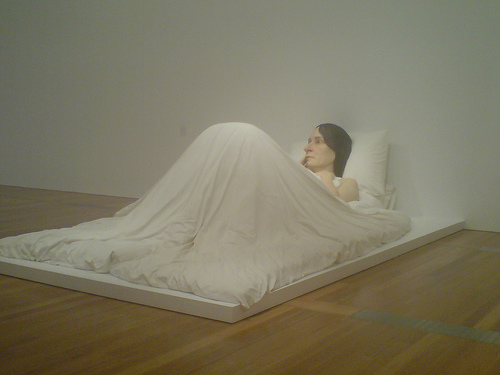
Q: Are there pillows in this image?
A: Yes, there is a pillow.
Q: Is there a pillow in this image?
A: Yes, there is a pillow.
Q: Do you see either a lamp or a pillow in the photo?
A: Yes, there is a pillow.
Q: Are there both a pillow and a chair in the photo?
A: No, there is a pillow but no chairs.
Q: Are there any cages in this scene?
A: No, there are no cages.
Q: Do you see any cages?
A: No, there are no cages.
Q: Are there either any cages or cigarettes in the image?
A: No, there are no cages or cigarettes.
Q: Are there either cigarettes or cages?
A: No, there are no cages or cigarettes.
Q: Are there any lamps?
A: No, there are no lamps.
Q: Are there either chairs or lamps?
A: No, there are no lamps or chairs.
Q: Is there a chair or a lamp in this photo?
A: No, there are no lamps or chairs.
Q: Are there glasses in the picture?
A: No, there are no glasses.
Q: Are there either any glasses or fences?
A: No, there are no glasses or fences.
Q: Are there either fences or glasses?
A: No, there are no glasses or fences.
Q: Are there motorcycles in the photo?
A: No, there are no motorcycles.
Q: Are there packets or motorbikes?
A: No, there are no motorbikes or packets.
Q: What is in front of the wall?
A: The sculpture is in front of the wall.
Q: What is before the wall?
A: The sculpture is in front of the wall.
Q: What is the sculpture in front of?
A: The sculpture is in front of the wall.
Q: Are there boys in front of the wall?
A: No, there is a sculpture in front of the wall.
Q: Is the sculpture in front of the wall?
A: Yes, the sculpture is in front of the wall.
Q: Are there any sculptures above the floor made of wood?
A: Yes, there is a sculpture above the floor.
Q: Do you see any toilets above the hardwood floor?
A: No, there is a sculpture above the floor.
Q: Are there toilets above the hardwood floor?
A: No, there is a sculpture above the floor.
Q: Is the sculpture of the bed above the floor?
A: Yes, the sculpture is above the floor.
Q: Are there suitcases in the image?
A: No, there are no suitcases.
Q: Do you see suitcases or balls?
A: No, there are no suitcases or balls.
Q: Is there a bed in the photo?
A: Yes, there is a bed.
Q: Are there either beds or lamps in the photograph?
A: Yes, there is a bed.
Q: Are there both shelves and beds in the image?
A: No, there is a bed but no shelves.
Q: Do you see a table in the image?
A: No, there are no tables.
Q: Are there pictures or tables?
A: No, there are no tables or pictures.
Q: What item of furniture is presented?
A: The piece of furniture is a bed.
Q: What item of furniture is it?
A: The piece of furniture is a bed.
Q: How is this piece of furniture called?
A: That is a bed.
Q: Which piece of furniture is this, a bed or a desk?
A: That is a bed.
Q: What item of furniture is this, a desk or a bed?
A: That is a bed.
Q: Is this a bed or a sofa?
A: This is a bed.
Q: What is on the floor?
A: The bed is on the floor.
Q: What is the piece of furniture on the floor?
A: The piece of furniture is a bed.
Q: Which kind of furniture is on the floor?
A: The piece of furniture is a bed.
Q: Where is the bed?
A: The bed is on the floor.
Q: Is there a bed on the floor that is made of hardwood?
A: Yes, there is a bed on the floor.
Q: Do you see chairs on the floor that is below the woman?
A: No, there is a bed on the floor.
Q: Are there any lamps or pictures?
A: No, there are no lamps or pictures.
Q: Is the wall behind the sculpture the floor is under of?
A: Yes, the wall is behind the sculpture.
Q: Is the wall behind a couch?
A: No, the wall is behind the sculpture.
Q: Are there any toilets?
A: No, there are no toilets.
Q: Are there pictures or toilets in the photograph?
A: No, there are no toilets or pictures.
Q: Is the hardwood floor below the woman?
A: Yes, the floor is below the woman.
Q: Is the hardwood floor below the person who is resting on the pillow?
A: Yes, the floor is below the woman.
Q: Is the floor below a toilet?
A: No, the floor is below the woman.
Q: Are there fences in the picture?
A: No, there are no fences.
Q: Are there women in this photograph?
A: Yes, there is a woman.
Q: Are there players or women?
A: Yes, there is a woman.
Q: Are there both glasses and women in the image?
A: No, there is a woman but no glasses.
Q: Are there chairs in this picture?
A: No, there are no chairs.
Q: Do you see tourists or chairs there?
A: No, there are no chairs or tourists.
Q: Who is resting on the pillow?
A: The woman is resting on the pillow.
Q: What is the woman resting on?
A: The woman is resting on the pillow.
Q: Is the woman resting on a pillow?
A: Yes, the woman is resting on a pillow.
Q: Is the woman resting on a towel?
A: No, the woman is resting on a pillow.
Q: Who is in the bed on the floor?
A: The woman is in the bed.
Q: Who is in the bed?
A: The woman is in the bed.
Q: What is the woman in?
A: The woman is in the bed.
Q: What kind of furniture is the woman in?
A: The woman is in the bed.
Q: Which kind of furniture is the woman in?
A: The woman is in the bed.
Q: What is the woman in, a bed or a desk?
A: The woman is in a bed.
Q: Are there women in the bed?
A: Yes, there is a woman in the bed.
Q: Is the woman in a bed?
A: Yes, the woman is in a bed.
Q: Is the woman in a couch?
A: No, the woman is in a bed.